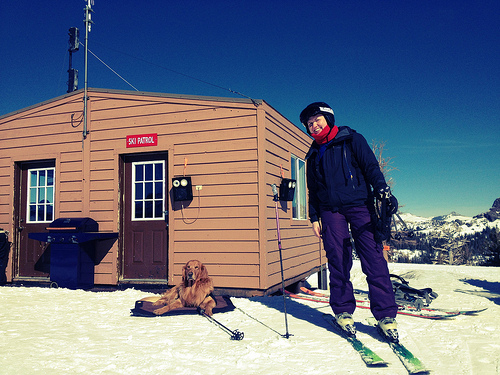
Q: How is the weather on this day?
A: It is clear.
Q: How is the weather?
A: It is clear.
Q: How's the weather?
A: It is clear.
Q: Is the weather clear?
A: Yes, it is clear.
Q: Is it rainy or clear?
A: It is clear.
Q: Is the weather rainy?
A: No, it is clear.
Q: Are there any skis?
A: Yes, there are skis.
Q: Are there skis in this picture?
A: Yes, there are skis.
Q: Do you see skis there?
A: Yes, there are skis.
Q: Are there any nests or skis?
A: Yes, there are skis.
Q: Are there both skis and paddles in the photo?
A: No, there are skis but no paddles.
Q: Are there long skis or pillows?
A: Yes, there are long skis.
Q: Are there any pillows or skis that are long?
A: Yes, the skis are long.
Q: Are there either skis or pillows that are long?
A: Yes, the skis are long.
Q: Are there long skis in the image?
A: Yes, there are long skis.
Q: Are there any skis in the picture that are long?
A: Yes, there are skis that are long.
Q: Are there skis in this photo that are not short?
A: Yes, there are long skis.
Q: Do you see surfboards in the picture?
A: No, there are no surfboards.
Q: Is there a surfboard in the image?
A: No, there are no surfboards.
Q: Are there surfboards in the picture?
A: No, there are no surfboards.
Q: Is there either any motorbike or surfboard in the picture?
A: No, there are no surfboards or motorcycles.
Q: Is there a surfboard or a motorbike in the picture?
A: No, there are no surfboards or motorcycles.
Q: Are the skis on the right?
A: Yes, the skis are on the right of the image.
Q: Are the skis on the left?
A: No, the skis are on the right of the image.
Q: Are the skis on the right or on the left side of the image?
A: The skis are on the right of the image.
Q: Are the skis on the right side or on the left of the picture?
A: The skis are on the right of the image.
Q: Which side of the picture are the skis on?
A: The skis are on the right of the image.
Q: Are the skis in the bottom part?
A: Yes, the skis are in the bottom of the image.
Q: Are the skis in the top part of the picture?
A: No, the skis are in the bottom of the image.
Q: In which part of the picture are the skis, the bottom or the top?
A: The skis are in the bottom of the image.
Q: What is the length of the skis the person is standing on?
A: The skis are long.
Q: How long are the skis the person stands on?
A: The skis are long.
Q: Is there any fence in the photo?
A: No, there are no fences.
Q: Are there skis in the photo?
A: Yes, there are skis.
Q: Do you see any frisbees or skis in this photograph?
A: Yes, there are skis.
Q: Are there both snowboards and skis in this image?
A: No, there are skis but no snowboards.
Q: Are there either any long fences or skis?
A: Yes, there are long skis.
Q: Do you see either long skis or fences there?
A: Yes, there are long skis.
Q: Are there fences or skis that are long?
A: Yes, the skis are long.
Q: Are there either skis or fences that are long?
A: Yes, the skis are long.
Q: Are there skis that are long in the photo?
A: Yes, there are long skis.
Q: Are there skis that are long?
A: Yes, there are skis that are long.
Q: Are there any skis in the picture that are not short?
A: Yes, there are long skis.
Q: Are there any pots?
A: No, there are no pots.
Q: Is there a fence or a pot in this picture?
A: No, there are no pots or fences.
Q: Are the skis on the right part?
A: Yes, the skis are on the right of the image.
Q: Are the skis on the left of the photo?
A: No, the skis are on the right of the image.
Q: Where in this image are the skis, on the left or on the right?
A: The skis are on the right of the image.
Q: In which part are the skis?
A: The skis are on the right of the image.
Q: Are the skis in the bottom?
A: Yes, the skis are in the bottom of the image.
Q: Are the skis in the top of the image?
A: No, the skis are in the bottom of the image.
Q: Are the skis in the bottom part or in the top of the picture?
A: The skis are in the bottom of the image.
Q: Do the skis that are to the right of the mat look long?
A: Yes, the skis are long.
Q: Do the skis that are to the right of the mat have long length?
A: Yes, the skis are long.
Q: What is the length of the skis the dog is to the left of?
A: The skis are long.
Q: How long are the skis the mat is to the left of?
A: The skis are long.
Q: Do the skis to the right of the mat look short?
A: No, the skis are long.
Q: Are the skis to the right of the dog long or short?
A: The skis are long.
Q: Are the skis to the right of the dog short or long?
A: The skis are long.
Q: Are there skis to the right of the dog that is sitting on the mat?
A: Yes, there are skis to the right of the dog.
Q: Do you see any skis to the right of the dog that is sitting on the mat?
A: Yes, there are skis to the right of the dog.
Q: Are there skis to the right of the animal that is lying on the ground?
A: Yes, there are skis to the right of the dog.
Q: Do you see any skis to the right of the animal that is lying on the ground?
A: Yes, there are skis to the right of the dog.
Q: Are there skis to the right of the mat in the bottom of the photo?
A: Yes, there are skis to the right of the mat.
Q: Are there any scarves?
A: Yes, there is a scarf.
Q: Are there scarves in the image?
A: Yes, there is a scarf.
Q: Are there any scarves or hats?
A: Yes, there is a scarf.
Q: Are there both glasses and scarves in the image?
A: No, there is a scarf but no glasses.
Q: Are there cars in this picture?
A: No, there are no cars.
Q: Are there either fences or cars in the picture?
A: No, there are no cars or fences.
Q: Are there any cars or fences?
A: No, there are no cars or fences.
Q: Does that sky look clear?
A: Yes, the sky is clear.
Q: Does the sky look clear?
A: Yes, the sky is clear.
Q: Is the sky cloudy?
A: No, the sky is clear.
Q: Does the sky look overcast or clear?
A: The sky is clear.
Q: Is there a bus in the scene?
A: No, there are no buses.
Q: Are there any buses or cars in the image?
A: No, there are no buses or cars.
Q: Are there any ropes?
A: No, there are no ropes.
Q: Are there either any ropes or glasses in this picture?
A: No, there are no ropes or glasses.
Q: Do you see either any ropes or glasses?
A: No, there are no ropes or glasses.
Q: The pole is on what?
A: The pole is on the building.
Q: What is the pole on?
A: The pole is on the building.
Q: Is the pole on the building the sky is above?
A: Yes, the pole is on the building.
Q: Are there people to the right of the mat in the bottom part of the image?
A: Yes, there is a person to the right of the mat.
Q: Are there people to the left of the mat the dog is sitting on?
A: No, the person is to the right of the mat.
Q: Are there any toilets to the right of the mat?
A: No, there is a person to the right of the mat.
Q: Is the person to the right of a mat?
A: Yes, the person is to the right of a mat.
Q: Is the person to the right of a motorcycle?
A: No, the person is to the right of a mat.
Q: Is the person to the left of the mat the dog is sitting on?
A: No, the person is to the right of the mat.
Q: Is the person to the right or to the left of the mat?
A: The person is to the right of the mat.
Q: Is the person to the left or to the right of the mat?
A: The person is to the right of the mat.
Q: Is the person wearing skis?
A: Yes, the person is wearing skis.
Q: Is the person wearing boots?
A: No, the person is wearing skis.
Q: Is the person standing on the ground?
A: Yes, the person is standing on the ground.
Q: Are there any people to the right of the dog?
A: Yes, there is a person to the right of the dog.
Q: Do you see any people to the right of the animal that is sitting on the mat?
A: Yes, there is a person to the right of the dog.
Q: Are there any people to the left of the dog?
A: No, the person is to the right of the dog.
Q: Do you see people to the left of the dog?
A: No, the person is to the right of the dog.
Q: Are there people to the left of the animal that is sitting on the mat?
A: No, the person is to the right of the dog.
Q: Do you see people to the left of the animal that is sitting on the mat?
A: No, the person is to the right of the dog.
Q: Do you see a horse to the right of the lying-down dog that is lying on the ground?
A: No, there is a person to the right of the dog.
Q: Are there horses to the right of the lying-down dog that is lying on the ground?
A: No, there is a person to the right of the dog.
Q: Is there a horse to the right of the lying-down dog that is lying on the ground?
A: No, there is a person to the right of the dog.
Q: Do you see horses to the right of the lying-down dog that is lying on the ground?
A: No, there is a person to the right of the dog.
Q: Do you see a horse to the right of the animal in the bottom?
A: No, there is a person to the right of the dog.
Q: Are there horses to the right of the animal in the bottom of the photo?
A: No, there is a person to the right of the dog.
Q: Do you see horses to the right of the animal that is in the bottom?
A: No, there is a person to the right of the dog.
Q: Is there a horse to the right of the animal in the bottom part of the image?
A: No, there is a person to the right of the dog.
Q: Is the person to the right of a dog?
A: Yes, the person is to the right of a dog.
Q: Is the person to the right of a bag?
A: No, the person is to the right of a dog.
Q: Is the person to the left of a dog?
A: No, the person is to the right of a dog.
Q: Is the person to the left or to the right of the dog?
A: The person is to the right of the dog.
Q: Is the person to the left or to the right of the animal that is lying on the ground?
A: The person is to the right of the dog.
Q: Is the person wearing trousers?
A: Yes, the person is wearing trousers.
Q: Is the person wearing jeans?
A: No, the person is wearing trousers.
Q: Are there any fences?
A: No, there are no fences.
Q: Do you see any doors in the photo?
A: Yes, there are doors.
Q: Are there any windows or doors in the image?
A: Yes, there are doors.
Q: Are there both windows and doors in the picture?
A: Yes, there are both doors and a window.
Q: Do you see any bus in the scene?
A: No, there are no buses.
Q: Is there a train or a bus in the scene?
A: No, there are no buses or trains.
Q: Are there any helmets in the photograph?
A: Yes, there is a helmet.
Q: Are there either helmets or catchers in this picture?
A: Yes, there is a helmet.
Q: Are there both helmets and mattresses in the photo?
A: No, there is a helmet but no mattresses.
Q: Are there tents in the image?
A: No, there are no tents.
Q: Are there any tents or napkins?
A: No, there are no tents or napkins.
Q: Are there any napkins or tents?
A: No, there are no tents or napkins.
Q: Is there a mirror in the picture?
A: No, there are no mirrors.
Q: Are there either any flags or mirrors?
A: No, there are no mirrors or flags.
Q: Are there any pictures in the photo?
A: No, there are no pictures.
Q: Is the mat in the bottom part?
A: Yes, the mat is in the bottom of the image.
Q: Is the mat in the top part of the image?
A: No, the mat is in the bottom of the image.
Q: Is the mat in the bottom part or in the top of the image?
A: The mat is in the bottom of the image.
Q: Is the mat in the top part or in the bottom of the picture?
A: The mat is in the bottom of the image.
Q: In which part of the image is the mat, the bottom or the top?
A: The mat is in the bottom of the image.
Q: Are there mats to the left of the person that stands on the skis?
A: Yes, there is a mat to the left of the person.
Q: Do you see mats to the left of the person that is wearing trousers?
A: Yes, there is a mat to the left of the person.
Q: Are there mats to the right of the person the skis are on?
A: No, the mat is to the left of the person.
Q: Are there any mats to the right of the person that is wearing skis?
A: No, the mat is to the left of the person.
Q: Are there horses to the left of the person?
A: No, there is a mat to the left of the person.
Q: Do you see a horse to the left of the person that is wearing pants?
A: No, there is a mat to the left of the person.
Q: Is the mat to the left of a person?
A: Yes, the mat is to the left of a person.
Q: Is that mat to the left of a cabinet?
A: No, the mat is to the left of a person.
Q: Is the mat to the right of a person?
A: No, the mat is to the left of a person.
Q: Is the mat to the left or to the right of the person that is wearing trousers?
A: The mat is to the left of the person.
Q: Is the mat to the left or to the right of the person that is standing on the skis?
A: The mat is to the left of the person.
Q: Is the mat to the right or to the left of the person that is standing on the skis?
A: The mat is to the left of the person.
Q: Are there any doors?
A: Yes, there is a door.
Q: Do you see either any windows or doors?
A: Yes, there is a door.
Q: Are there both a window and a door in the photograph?
A: Yes, there are both a door and a window.